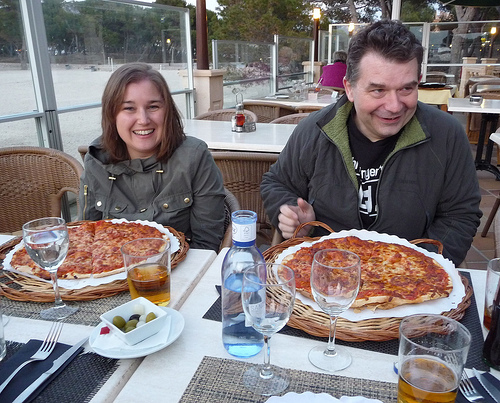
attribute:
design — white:
[350, 152, 382, 218]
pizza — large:
[5, 219, 170, 277]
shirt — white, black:
[341, 106, 408, 232]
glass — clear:
[244, 271, 285, 391]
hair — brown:
[70, 55, 203, 162]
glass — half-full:
[117, 236, 178, 307]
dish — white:
[96, 293, 168, 347]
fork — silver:
[1, 316, 69, 360]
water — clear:
[21, 212, 87, 329]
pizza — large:
[298, 215, 498, 371]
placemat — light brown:
[173, 356, 398, 401]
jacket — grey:
[97, 134, 220, 230]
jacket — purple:
[312, 61, 339, 104]